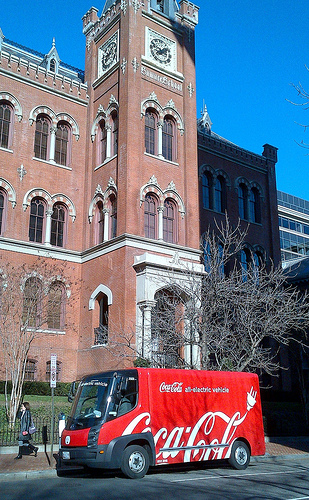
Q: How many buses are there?
A: One.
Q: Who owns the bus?
A: Coca-cola.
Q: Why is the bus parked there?
A: It is making a delivery.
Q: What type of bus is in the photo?
A: A delivery bus.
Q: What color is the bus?
A: Red.